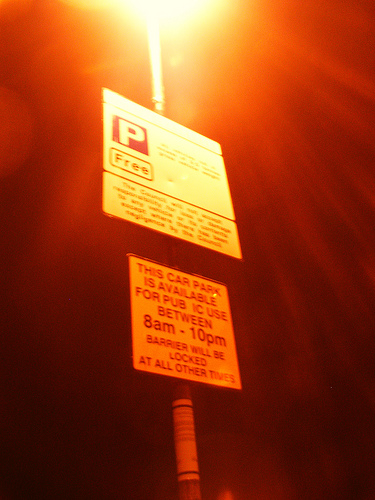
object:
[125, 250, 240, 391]
writing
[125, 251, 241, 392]
sign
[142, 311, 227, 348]
times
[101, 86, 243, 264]
square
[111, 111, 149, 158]
p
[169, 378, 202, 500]
pole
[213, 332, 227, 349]
letters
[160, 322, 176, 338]
letters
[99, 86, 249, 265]
sign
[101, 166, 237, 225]
line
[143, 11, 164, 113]
pole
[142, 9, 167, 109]
light